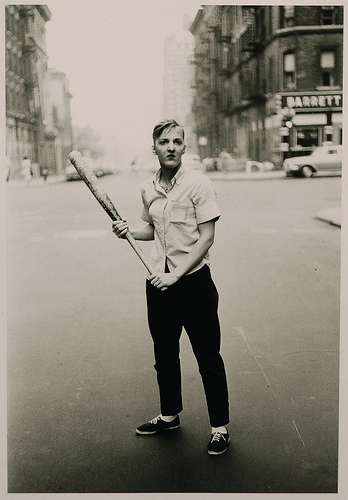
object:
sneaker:
[206, 425, 230, 456]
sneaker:
[134, 414, 182, 437]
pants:
[144, 261, 230, 426]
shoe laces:
[210, 432, 227, 446]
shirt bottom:
[149, 262, 211, 284]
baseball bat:
[68, 150, 169, 295]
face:
[154, 123, 183, 166]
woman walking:
[19, 155, 34, 182]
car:
[282, 143, 341, 179]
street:
[2, 172, 341, 493]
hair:
[151, 115, 186, 144]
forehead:
[158, 125, 182, 137]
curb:
[211, 169, 341, 184]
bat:
[68, 148, 168, 294]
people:
[40, 163, 50, 182]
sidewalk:
[0, 168, 70, 186]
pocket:
[168, 199, 188, 224]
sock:
[159, 413, 179, 421]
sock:
[209, 425, 228, 437]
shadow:
[7, 433, 339, 494]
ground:
[2, 166, 341, 492]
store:
[265, 91, 343, 169]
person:
[136, 118, 234, 460]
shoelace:
[148, 415, 161, 427]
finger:
[118, 227, 129, 239]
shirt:
[139, 163, 220, 279]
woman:
[19, 155, 34, 186]